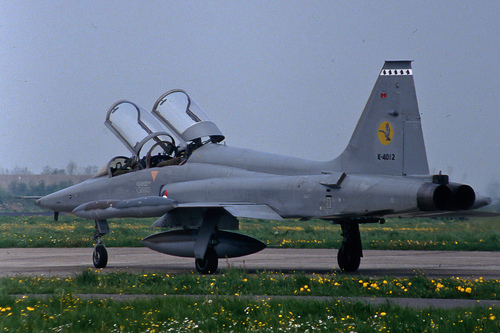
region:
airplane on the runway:
[29, 59, 464, 279]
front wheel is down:
[82, 220, 114, 267]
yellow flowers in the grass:
[3, 273, 494, 332]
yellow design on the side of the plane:
[371, 119, 399, 149]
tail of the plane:
[333, 53, 498, 262]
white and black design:
[378, 63, 418, 81]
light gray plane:
[25, 55, 488, 288]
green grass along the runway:
[0, 270, 499, 332]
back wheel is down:
[325, 224, 367, 271]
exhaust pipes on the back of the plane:
[418, 173, 488, 219]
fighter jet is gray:
[25, 34, 490, 284]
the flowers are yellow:
[257, 272, 365, 296]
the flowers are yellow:
[276, 278, 336, 298]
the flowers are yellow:
[274, 262, 396, 312]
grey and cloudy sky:
[222, 9, 307, 98]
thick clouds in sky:
[213, 30, 325, 117]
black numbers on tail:
[358, 154, 415, 169]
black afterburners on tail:
[404, 166, 493, 224]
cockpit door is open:
[111, 85, 214, 172]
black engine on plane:
[120, 198, 245, 275]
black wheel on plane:
[90, 239, 118, 266]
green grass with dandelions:
[115, 269, 476, 311]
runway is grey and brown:
[112, 242, 464, 269]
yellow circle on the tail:
[378, 120, 397, 149]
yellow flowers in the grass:
[24, 271, 104, 329]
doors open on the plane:
[100, 80, 241, 182]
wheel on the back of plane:
[332, 239, 369, 281]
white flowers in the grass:
[281, 314, 354, 331]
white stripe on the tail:
[385, 65, 431, 80]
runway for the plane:
[16, 230, 477, 290]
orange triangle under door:
[145, 160, 167, 191]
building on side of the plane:
[7, 155, 116, 213]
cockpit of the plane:
[72, 120, 232, 192]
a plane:
[35, 56, 497, 275]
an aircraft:
[22, 57, 492, 284]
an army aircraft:
[31, 53, 481, 279]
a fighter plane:
[33, 55, 488, 275]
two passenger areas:
[94, 74, 235, 181]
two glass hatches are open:
[98, 88, 232, 178]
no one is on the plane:
[31, 59, 493, 274]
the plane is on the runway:
[22, 53, 492, 270]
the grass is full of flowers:
[1, 268, 498, 332]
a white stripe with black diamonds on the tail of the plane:
[375, 58, 424, 80]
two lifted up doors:
[92, 77, 222, 175]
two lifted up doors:
[94, 70, 221, 168]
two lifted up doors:
[97, 75, 230, 175]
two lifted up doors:
[96, 79, 222, 171]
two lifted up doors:
[95, 80, 218, 176]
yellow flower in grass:
[1, 305, 8, 312]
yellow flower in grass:
[4, 305, 10, 309]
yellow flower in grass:
[24, 305, 34, 314]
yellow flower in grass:
[463, 284, 475, 296]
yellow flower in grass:
[435, 280, 444, 287]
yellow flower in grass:
[491, 311, 498, 316]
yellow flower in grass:
[301, 280, 308, 291]